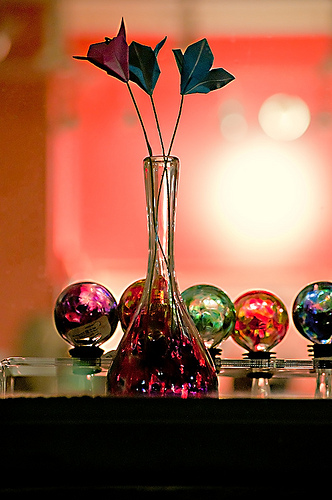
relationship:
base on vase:
[97, 324, 229, 388] [94, 153, 226, 402]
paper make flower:
[99, 48, 209, 84] [172, 36, 237, 95]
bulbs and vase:
[42, 270, 216, 442] [41, 261, 215, 436]